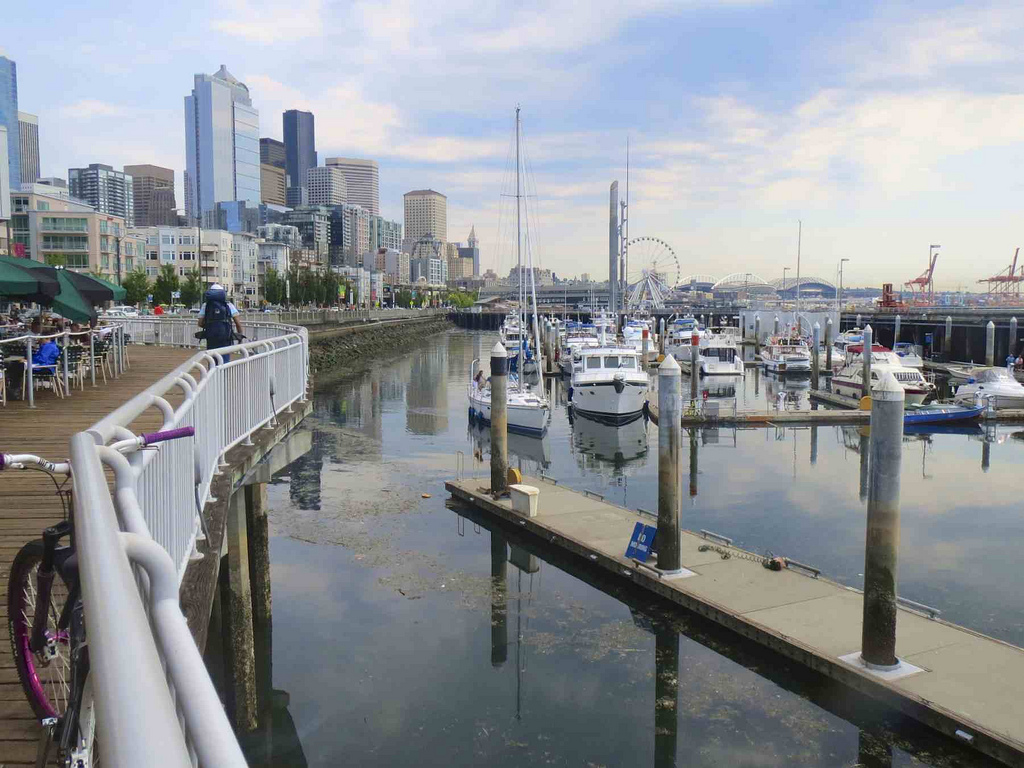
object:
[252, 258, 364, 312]
trees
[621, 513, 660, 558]
blue sign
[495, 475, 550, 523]
white container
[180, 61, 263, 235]
glass building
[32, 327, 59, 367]
blue shirt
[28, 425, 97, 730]
bicycle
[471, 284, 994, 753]
marina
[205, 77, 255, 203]
glass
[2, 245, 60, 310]
umbrella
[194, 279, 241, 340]
person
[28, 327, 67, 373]
person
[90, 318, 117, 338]
person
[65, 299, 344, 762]
rail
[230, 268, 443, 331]
street